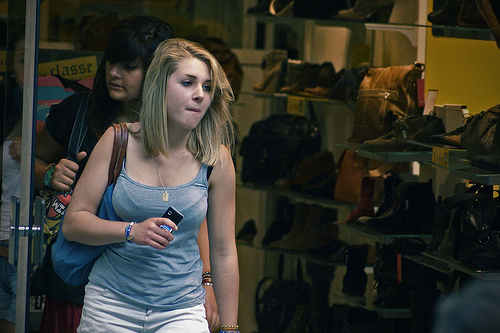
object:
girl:
[60, 36, 251, 333]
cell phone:
[153, 205, 186, 238]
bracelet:
[123, 219, 136, 244]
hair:
[135, 37, 239, 167]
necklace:
[146, 136, 190, 204]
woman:
[21, 17, 226, 333]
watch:
[39, 162, 56, 191]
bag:
[51, 122, 130, 288]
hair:
[83, 17, 175, 127]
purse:
[41, 92, 102, 252]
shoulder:
[65, 91, 112, 113]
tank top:
[88, 137, 210, 313]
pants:
[73, 276, 219, 333]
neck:
[162, 121, 193, 150]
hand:
[131, 214, 180, 250]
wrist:
[121, 221, 138, 246]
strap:
[108, 118, 133, 188]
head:
[431, 277, 500, 333]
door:
[9, 0, 44, 333]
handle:
[32, 198, 44, 268]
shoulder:
[100, 121, 146, 144]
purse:
[236, 110, 322, 194]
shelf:
[275, 187, 381, 211]